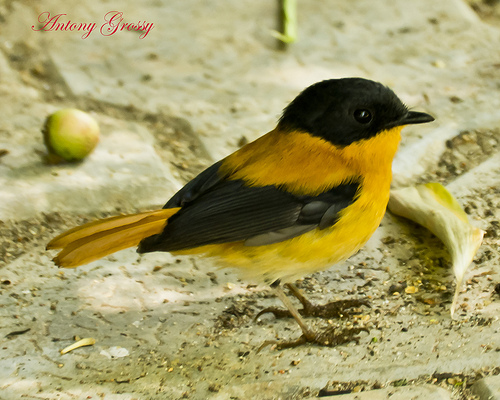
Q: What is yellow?
A: Bird.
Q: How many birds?
A: 1.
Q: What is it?
A: Bird.